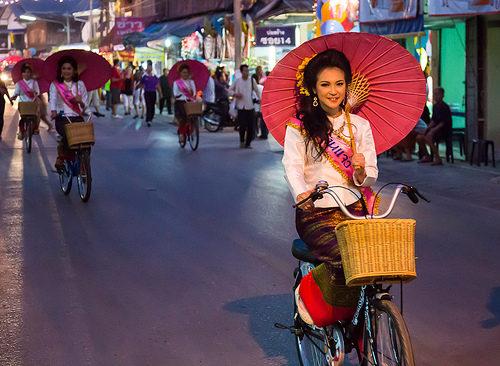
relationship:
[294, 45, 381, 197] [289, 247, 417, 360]
person on bike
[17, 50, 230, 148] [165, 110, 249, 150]
people on bikes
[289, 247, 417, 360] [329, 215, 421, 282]
bike has basket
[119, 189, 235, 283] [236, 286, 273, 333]
ground has shadow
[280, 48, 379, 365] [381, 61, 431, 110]
person holding umbrella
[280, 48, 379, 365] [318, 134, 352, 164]
person wearing sash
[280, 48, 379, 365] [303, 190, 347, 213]
person holding handlebar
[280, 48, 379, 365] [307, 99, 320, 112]
person wearing earrings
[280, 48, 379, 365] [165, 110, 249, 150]
person riding bikes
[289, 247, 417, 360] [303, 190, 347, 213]
bike has handlebar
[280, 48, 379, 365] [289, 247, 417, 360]
person riding bike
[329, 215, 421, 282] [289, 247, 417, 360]
basket on bike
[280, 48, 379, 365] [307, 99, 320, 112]
person has earrings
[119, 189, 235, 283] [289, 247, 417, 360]
ground has bike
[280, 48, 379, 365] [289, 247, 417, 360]
person of bike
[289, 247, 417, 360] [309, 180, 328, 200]
bike has bell